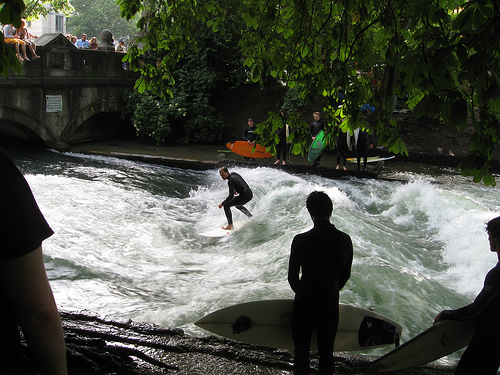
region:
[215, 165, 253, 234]
man in wetsuit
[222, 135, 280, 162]
orange surfboard of waiting person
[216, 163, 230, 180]
Man's head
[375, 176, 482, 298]
waves in the stream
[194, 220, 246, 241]
white surfboard in the water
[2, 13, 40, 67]
onlookers sitting on bridge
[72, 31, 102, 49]
onlookers standing on the bridge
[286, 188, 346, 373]
bystander near the stream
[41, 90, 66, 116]
white sign on the bridge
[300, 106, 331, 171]
bystander with green surfboard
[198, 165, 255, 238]
Man surfing on waves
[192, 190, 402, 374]
Man holding a surfboard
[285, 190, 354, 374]
Man standing in a black wetsuit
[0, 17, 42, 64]
Two people sitting on a bridge ledge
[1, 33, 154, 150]
Old stone bridge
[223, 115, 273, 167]
Man holding an orange surfboard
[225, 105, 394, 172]
Group of people with surfboards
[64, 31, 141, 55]
Spectators watching the surfer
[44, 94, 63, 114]
White sign hanging on a bridge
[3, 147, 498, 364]
River with white waves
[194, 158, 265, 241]
person on a surfboard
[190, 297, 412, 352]
white surfboard near the water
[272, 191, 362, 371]
person standing near the water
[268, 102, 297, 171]
person standing near the water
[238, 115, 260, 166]
person standing near the water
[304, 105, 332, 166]
person standing near the water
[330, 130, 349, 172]
person standing near the water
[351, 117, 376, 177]
person standing near the water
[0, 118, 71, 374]
person standing near the water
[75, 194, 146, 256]
white sea foam on wave surface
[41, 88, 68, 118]
white sign on side of stone bridge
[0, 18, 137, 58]
crowd watching surfers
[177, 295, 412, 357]
white fiberglass surfboard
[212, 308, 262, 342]
black design on surfboard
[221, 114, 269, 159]
person holding orange surfboard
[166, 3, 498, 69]
trees with green leaves hanging over water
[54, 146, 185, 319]
fast flowing water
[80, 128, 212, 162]
concrete path beside water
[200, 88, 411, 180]
row of surfers on shore of water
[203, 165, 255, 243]
man surfing in a wave pool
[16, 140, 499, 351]
large pool with waves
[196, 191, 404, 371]
person waiting to surf in wave pool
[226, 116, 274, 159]
person holding an orange surf board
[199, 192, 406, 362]
person holding a white surf board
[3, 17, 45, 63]
people sitting on concrete ledge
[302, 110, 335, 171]
person holding neon green surf board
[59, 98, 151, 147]
arch in concrete bridge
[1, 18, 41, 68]
people watching surfers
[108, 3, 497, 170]
leafy branches hanging over water